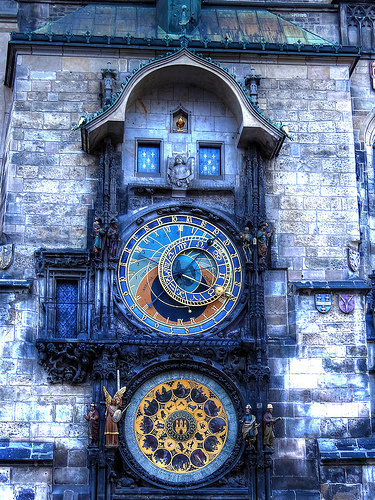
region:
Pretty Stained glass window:
[136, 139, 159, 173]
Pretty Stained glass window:
[197, 142, 221, 175]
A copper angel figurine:
[102, 384, 125, 445]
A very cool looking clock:
[117, 212, 243, 334]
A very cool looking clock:
[125, 368, 238, 482]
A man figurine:
[264, 403, 279, 448]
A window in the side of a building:
[53, 278, 78, 336]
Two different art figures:
[238, 222, 275, 267]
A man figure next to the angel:
[83, 402, 99, 446]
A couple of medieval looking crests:
[314, 294, 355, 314]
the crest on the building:
[304, 287, 364, 320]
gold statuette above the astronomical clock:
[166, 108, 191, 132]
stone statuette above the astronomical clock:
[155, 148, 200, 194]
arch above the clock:
[50, 52, 296, 175]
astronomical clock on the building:
[105, 203, 270, 338]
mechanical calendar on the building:
[113, 352, 244, 487]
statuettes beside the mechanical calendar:
[75, 371, 129, 454]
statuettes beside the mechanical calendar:
[235, 395, 280, 451]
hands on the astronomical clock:
[129, 235, 227, 307]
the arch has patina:
[85, 30, 292, 161]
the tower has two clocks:
[116, 151, 300, 424]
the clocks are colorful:
[95, 384, 206, 486]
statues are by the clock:
[90, 388, 161, 497]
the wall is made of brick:
[16, 415, 74, 493]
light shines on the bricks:
[299, 396, 356, 456]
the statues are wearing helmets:
[231, 390, 333, 462]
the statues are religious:
[77, 381, 153, 484]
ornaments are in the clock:
[146, 401, 227, 487]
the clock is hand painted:
[136, 391, 221, 483]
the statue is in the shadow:
[75, 391, 148, 495]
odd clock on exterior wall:
[106, 200, 263, 352]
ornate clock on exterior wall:
[102, 193, 249, 353]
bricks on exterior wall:
[282, 308, 373, 438]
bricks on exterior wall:
[277, 80, 355, 270]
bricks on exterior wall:
[15, 73, 87, 255]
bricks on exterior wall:
[9, 343, 72, 443]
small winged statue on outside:
[101, 386, 128, 444]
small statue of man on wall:
[263, 398, 282, 448]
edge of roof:
[6, 25, 361, 58]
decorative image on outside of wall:
[155, 152, 201, 193]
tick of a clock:
[167, 213, 186, 233]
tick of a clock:
[185, 210, 199, 241]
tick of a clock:
[175, 304, 194, 329]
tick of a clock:
[188, 311, 200, 336]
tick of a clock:
[148, 301, 160, 318]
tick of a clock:
[128, 285, 144, 304]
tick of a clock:
[117, 269, 139, 275]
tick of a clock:
[123, 250, 148, 265]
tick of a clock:
[138, 236, 154, 245]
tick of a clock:
[150, 223, 167, 240]